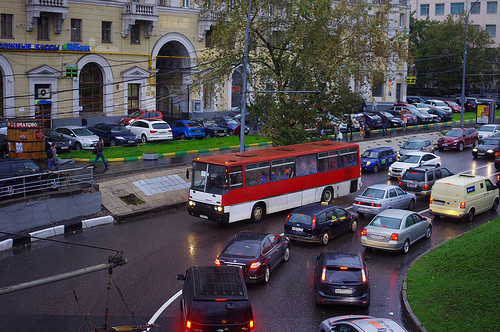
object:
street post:
[240, 2, 252, 152]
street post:
[458, 8, 467, 127]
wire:
[0, 37, 239, 130]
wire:
[0, 32, 462, 127]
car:
[360, 208, 432, 254]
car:
[313, 251, 371, 308]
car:
[125, 119, 173, 143]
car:
[175, 265, 254, 332]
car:
[437, 127, 480, 152]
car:
[214, 230, 291, 284]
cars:
[174, 125, 500, 332]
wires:
[0, 40, 490, 124]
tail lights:
[361, 228, 399, 241]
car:
[119, 111, 163, 126]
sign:
[476, 103, 490, 124]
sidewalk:
[399, 114, 499, 131]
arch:
[152, 32, 199, 121]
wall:
[222, 68, 290, 129]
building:
[0, 0, 410, 139]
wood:
[37, 147, 43, 157]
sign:
[15, 142, 23, 154]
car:
[53, 126, 104, 151]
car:
[169, 120, 205, 140]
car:
[87, 123, 139, 147]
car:
[362, 112, 383, 130]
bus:
[186, 140, 363, 224]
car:
[428, 172, 500, 223]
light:
[361, 266, 366, 283]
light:
[321, 265, 327, 281]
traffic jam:
[175, 124, 500, 332]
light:
[249, 261, 262, 270]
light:
[214, 258, 220, 266]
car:
[314, 314, 410, 332]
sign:
[7, 119, 46, 160]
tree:
[180, 0, 413, 150]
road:
[2, 138, 498, 332]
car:
[284, 203, 359, 246]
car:
[352, 183, 417, 215]